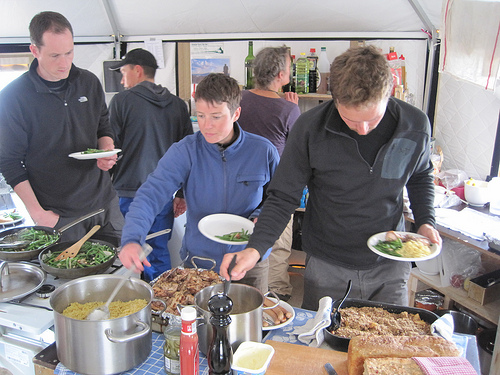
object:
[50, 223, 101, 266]
utensil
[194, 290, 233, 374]
grinder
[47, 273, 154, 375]
pot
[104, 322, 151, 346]
handle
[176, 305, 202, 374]
bottle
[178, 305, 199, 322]
lid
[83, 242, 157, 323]
spoon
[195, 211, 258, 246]
plate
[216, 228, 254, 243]
food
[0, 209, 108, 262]
pan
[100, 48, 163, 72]
cap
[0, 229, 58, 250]
beans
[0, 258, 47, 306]
lid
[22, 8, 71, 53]
hair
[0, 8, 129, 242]
guy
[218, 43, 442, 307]
guy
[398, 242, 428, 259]
food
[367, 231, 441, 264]
plate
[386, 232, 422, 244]
food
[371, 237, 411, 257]
food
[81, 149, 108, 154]
food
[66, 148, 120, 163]
plate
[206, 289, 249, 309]
food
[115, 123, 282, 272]
sweater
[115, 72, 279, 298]
lady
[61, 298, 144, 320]
food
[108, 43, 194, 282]
guy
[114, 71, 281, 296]
person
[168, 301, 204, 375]
ketchup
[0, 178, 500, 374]
table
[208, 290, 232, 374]
pepper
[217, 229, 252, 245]
beans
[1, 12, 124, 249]
person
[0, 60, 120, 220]
grey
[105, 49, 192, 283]
person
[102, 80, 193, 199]
grey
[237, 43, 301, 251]
person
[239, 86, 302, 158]
grey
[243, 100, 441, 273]
grey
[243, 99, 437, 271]
shirt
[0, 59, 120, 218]
shirt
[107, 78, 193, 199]
shirt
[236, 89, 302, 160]
shirt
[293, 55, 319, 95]
food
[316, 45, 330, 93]
food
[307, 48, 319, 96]
food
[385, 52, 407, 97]
food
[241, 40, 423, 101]
shelf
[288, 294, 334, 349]
towel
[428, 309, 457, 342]
towel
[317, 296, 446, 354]
pan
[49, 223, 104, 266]
spoon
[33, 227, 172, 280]
pan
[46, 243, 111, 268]
salad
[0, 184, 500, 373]
buffet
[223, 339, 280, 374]
container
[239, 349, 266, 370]
margerine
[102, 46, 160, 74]
hat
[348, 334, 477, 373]
bread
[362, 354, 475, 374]
loaf